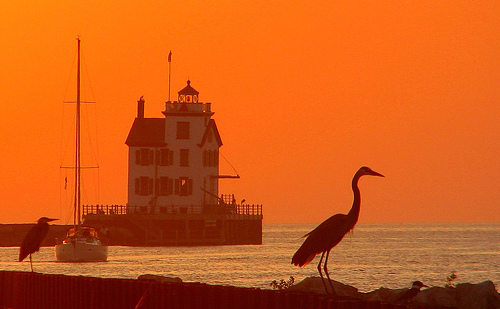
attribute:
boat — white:
[56, 27, 112, 260]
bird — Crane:
[290, 164, 383, 299]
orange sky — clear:
[285, 84, 389, 126]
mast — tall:
[73, 36, 80, 236]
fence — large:
[80, 202, 262, 222]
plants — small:
[267, 275, 297, 290]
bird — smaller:
[18, 214, 58, 271]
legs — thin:
[315, 246, 344, 301]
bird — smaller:
[388, 278, 435, 306]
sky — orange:
[1, 0, 498, 222]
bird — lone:
[264, 132, 406, 300]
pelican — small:
[17, 213, 59, 275]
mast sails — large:
[72, 38, 84, 230]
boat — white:
[52, 33, 109, 261]